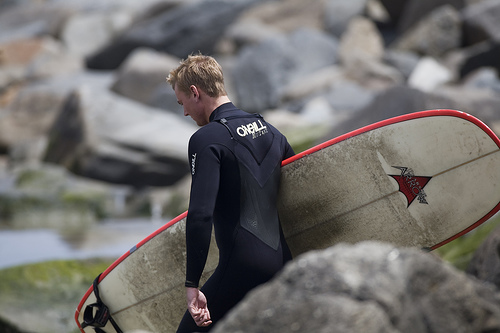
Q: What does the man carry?
A: A surfboard.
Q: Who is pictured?
A: A surfer.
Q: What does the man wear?
A: Wetsuit.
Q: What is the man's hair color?
A: Blonde.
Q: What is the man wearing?
A: Black wetsuit.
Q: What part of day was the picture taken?
A: Daylight.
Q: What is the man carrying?
A: Surfboard.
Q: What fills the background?
A: Large rocks.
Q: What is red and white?
A: Surfboard.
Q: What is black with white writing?
A: Wetsuit.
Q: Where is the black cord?
A: On the surfboard.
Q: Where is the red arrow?
A: Surfboard.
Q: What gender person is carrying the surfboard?
A: Male.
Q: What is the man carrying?
A: Surfboard.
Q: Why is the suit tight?
A: Protection of body.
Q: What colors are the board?
A: Red and white.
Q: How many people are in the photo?
A: One.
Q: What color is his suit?
A: Black.